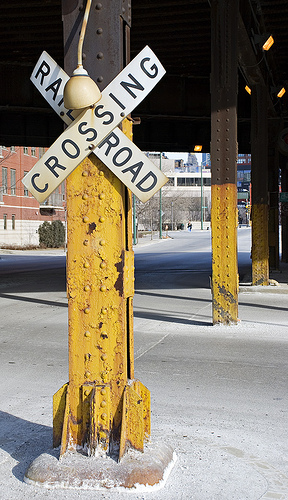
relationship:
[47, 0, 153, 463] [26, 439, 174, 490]
pole has base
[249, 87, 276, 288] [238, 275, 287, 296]
pole has base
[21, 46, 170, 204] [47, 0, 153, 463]
sign on pole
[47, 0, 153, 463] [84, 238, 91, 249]
pole has rivets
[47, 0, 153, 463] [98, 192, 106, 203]
pole has rivets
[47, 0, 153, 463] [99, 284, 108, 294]
pole has rivets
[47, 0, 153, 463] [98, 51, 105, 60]
pole has rivets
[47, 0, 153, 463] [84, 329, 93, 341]
pole has rivets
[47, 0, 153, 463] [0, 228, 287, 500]
pole on street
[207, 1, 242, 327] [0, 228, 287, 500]
pole on street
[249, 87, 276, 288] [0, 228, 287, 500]
pole on street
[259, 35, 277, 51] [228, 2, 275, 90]
lamp on pole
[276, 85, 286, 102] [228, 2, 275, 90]
lamp on pole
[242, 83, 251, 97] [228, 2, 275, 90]
lamp on pole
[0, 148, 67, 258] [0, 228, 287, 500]
building near street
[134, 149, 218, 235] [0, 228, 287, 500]
building near street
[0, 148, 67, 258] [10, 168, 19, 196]
building has window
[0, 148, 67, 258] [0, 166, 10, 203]
building has window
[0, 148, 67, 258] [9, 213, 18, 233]
building has window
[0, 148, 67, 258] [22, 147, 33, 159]
building has window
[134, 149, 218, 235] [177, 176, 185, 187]
building has window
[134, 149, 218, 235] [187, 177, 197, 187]
building has window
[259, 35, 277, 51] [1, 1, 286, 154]
lamp on ceiling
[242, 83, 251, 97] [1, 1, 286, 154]
lamp on ceiling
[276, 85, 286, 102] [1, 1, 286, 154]
lamp on ceiling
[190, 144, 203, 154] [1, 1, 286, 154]
lamp on ceiling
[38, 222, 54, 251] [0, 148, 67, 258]
bush near building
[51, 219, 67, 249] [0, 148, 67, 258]
bush near building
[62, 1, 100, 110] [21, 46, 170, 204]
light in front of sign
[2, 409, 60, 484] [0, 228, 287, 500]
shadow on street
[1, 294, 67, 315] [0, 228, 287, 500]
shadow on street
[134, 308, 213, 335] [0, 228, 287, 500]
shadow on street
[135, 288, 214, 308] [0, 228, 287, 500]
shadow on street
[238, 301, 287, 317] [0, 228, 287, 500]
shadow on street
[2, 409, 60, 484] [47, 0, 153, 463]
shadow from pole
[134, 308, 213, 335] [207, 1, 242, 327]
shadow from pole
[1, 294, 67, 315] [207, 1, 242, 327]
shadow from pole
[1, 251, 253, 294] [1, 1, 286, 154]
shadow from bridge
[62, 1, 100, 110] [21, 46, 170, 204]
light over sign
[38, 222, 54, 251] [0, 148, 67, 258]
shrub in front of building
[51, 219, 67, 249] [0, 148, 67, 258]
shrub in front of building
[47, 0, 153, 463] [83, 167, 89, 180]
pole has bolt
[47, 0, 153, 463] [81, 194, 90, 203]
pole has bolt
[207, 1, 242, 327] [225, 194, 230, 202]
pole has bolt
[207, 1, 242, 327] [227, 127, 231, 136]
pole has bolt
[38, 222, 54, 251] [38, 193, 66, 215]
bush under balcony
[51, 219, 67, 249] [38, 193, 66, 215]
bush under balcony